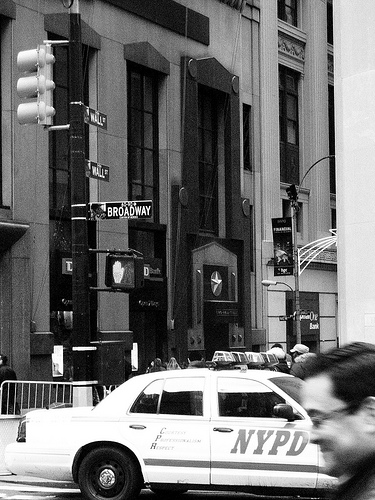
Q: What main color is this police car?
A: White.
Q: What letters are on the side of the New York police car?
A: NYPD.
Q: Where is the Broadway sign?
A: On a pole.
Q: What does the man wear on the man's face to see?
A: Glasses.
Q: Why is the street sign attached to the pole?
A: Directions.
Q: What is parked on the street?
A: A police vehicle.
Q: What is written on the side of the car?
A: NYPD.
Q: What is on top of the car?
A: Lights.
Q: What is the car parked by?
A: A street sign.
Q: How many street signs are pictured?
A: 4.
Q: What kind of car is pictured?
A: Cop.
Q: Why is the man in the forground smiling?
A: Happy.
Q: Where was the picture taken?
A: New york.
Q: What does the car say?
A: Nypd.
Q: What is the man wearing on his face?
A: Glasses.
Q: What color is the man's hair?
A: Brown.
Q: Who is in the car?
A: Police.